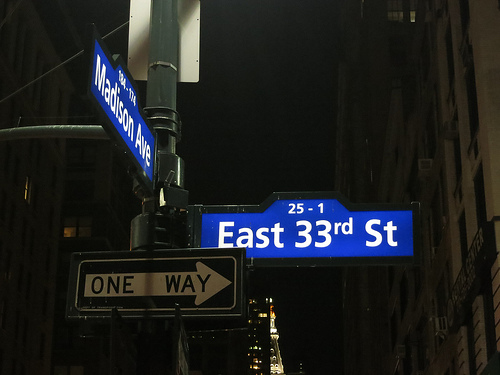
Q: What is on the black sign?
A: White arrow.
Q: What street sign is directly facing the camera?
A: East 33rd St.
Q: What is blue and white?
A: The sign.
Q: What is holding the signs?
A: The pole.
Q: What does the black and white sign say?
A: One way.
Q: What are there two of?
A: Blue and white signs.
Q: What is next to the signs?
A: Building.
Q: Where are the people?
A: No people.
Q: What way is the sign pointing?
A: Right.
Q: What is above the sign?
A: A pole.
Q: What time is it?
A: Night.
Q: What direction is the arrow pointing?
A: Right.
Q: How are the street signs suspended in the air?
A: Metal pole.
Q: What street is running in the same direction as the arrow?
A: East 33rd street.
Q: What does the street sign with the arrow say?
A: One way.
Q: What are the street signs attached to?
A: Metal pole.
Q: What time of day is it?
A: Evening.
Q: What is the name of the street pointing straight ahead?
A: Madison avenue.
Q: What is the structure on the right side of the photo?
A: Building.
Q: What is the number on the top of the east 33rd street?
A: 25-1.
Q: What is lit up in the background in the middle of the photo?
A: Building tower.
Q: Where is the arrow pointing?
A: Right.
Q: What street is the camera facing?
A: East 33rd.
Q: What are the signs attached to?
A: Metal pole.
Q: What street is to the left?
A: Madison.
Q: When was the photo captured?
A: During the night.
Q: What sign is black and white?
A: One way sign.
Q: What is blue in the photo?
A: Street signs.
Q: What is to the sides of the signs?
A: Buildings.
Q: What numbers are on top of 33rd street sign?
A: 25-1.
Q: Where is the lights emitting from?
A: A street light.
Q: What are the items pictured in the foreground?
A: Directional and street marker signs on a pole.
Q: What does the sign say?
A: One way.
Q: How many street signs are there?
A: Two.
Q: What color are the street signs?
A: Blue and white.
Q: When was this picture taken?
A: At night.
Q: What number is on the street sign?
A: 33.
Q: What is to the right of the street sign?
A: A tall building.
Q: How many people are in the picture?
A: None.